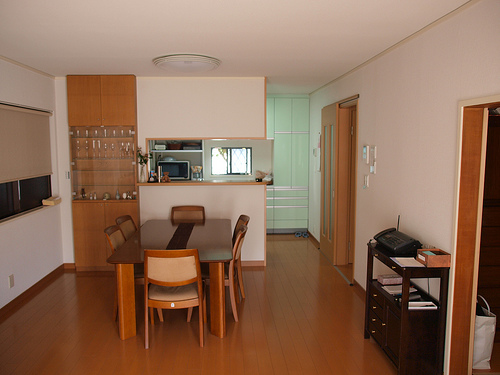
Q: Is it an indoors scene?
A: Yes, it is indoors.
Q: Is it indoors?
A: Yes, it is indoors.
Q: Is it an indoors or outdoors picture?
A: It is indoors.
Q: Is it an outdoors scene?
A: No, it is indoors.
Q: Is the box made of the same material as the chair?
A: Yes, both the box and the chair are made of wood.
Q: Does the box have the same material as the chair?
A: Yes, both the box and the chair are made of wood.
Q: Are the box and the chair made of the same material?
A: Yes, both the box and the chair are made of wood.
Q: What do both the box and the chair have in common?
A: The material, both the box and the chair are wooden.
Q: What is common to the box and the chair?
A: The material, both the box and the chair are wooden.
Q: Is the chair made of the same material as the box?
A: Yes, both the chair and the box are made of wood.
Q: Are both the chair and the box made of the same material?
A: Yes, both the chair and the box are made of wood.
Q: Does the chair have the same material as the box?
A: Yes, both the chair and the box are made of wood.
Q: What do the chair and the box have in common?
A: The material, both the chair and the box are wooden.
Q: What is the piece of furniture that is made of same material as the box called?
A: The piece of furniture is a chair.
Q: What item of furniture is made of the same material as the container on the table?
A: The chair is made of the same material as the box.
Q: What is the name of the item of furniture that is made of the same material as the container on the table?
A: The piece of furniture is a chair.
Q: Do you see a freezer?
A: No, there are no refrigerators.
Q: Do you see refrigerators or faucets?
A: No, there are no refrigerators or faucets.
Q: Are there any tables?
A: Yes, there is a table.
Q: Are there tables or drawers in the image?
A: Yes, there is a table.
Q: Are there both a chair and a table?
A: Yes, there are both a table and a chair.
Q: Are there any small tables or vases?
A: Yes, there is a small table.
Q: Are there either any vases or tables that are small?
A: Yes, the table is small.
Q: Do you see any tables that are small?
A: Yes, there is a small table.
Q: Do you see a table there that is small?
A: Yes, there is a table that is small.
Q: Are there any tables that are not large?
A: Yes, there is a small table.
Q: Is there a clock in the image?
A: No, there are no clocks.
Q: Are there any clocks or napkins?
A: No, there are no clocks or napkins.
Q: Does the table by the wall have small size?
A: Yes, the table is small.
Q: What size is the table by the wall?
A: The table is small.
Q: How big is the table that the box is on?
A: The table is small.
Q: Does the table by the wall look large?
A: No, the table is small.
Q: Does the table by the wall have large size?
A: No, the table is small.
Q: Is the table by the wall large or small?
A: The table is small.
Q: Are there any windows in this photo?
A: Yes, there is a window.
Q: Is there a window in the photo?
A: Yes, there is a window.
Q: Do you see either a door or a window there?
A: Yes, there is a window.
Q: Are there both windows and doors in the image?
A: Yes, there are both a window and a door.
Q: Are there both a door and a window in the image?
A: Yes, there are both a window and a door.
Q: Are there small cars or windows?
A: Yes, there is a small window.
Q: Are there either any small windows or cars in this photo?
A: Yes, there is a small window.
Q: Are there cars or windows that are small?
A: Yes, the window is small.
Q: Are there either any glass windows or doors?
A: Yes, there is a glass window.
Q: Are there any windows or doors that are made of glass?
A: Yes, the window is made of glass.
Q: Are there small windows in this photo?
A: Yes, there is a small window.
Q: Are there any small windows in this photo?
A: Yes, there is a small window.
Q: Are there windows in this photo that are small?
A: Yes, there is a small window.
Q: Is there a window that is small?
A: Yes, there is a window that is small.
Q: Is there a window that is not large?
A: Yes, there is a small window.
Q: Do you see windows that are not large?
A: Yes, there is a small window.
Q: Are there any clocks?
A: No, there are no clocks.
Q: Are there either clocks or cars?
A: No, there are no clocks or cars.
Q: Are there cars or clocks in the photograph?
A: No, there are no clocks or cars.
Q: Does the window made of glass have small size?
A: Yes, the window is small.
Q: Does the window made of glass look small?
A: Yes, the window is small.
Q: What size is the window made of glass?
A: The window is small.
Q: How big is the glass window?
A: The window is small.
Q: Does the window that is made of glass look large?
A: No, the window is small.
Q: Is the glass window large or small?
A: The window is small.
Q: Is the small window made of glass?
A: Yes, the window is made of glass.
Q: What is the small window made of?
A: The window is made of glass.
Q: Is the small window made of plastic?
A: No, the window is made of glass.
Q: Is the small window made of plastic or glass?
A: The window is made of glass.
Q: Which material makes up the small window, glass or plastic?
A: The window is made of glass.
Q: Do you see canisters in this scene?
A: No, there are no canisters.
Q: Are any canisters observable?
A: No, there are no canisters.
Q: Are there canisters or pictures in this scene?
A: No, there are no canisters or pictures.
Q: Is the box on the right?
A: Yes, the box is on the right of the image.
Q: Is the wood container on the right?
A: Yes, the box is on the right of the image.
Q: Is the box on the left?
A: No, the box is on the right of the image.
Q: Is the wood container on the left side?
A: No, the box is on the right of the image.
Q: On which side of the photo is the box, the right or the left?
A: The box is on the right of the image.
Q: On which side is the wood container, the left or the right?
A: The box is on the right of the image.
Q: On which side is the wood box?
A: The box is on the right of the image.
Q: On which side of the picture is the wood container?
A: The box is on the right of the image.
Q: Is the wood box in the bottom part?
A: Yes, the box is in the bottom of the image.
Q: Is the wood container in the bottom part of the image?
A: Yes, the box is in the bottom of the image.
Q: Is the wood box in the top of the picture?
A: No, the box is in the bottom of the image.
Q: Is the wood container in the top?
A: No, the box is in the bottom of the image.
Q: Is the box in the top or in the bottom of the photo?
A: The box is in the bottom of the image.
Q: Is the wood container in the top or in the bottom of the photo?
A: The box is in the bottom of the image.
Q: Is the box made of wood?
A: Yes, the box is made of wood.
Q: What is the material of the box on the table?
A: The box is made of wood.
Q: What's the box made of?
A: The box is made of wood.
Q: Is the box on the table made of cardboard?
A: No, the box is made of wood.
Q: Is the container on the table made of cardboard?
A: No, the box is made of wood.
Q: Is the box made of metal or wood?
A: The box is made of wood.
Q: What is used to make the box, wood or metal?
A: The box is made of wood.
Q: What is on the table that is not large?
A: The box is on the table.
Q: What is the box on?
A: The box is on the table.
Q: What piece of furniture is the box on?
A: The box is on the table.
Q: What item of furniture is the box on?
A: The box is on the table.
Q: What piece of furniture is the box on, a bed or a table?
A: The box is on a table.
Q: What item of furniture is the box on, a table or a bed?
A: The box is on a table.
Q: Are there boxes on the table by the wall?
A: Yes, there is a box on the table.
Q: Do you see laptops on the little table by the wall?
A: No, there is a box on the table.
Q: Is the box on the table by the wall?
A: Yes, the box is on the table.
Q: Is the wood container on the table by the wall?
A: Yes, the box is on the table.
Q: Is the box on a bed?
A: No, the box is on the table.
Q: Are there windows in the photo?
A: Yes, there is a window.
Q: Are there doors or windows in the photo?
A: Yes, there is a window.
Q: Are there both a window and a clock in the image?
A: No, there is a window but no clocks.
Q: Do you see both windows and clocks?
A: No, there is a window but no clocks.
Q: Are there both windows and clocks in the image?
A: No, there is a window but no clocks.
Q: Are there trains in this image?
A: No, there are no trains.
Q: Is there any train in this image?
A: No, there are no trains.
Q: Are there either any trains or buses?
A: No, there are no trains or buses.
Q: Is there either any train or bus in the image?
A: No, there are no trains or buses.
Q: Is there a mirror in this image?
A: No, there are no mirrors.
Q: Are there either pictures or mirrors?
A: No, there are no mirrors or pictures.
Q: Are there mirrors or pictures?
A: No, there are no mirrors or pictures.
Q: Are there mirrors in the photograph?
A: No, there are no mirrors.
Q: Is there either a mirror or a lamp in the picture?
A: No, there are no mirrors or lamps.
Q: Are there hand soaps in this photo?
A: No, there are no hand soaps.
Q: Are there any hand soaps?
A: No, there are no hand soaps.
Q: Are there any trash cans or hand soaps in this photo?
A: No, there are no hand soaps or trash cans.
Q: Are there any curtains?
A: No, there are no curtains.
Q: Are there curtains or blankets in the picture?
A: No, there are no curtains or blankets.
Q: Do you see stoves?
A: No, there are no stoves.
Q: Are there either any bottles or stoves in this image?
A: No, there are no stoves or bottles.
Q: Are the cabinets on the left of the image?
A: Yes, the cabinets are on the left of the image.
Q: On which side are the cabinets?
A: The cabinets are on the left of the image.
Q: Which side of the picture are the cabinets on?
A: The cabinets are on the left of the image.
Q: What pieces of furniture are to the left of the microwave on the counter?
A: The pieces of furniture are cabinets.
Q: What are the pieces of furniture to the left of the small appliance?
A: The pieces of furniture are cabinets.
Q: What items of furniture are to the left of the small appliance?
A: The pieces of furniture are cabinets.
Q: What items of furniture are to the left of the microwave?
A: The pieces of furniture are cabinets.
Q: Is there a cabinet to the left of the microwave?
A: Yes, there are cabinets to the left of the microwave.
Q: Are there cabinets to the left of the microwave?
A: Yes, there are cabinets to the left of the microwave.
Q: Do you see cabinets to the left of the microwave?
A: Yes, there are cabinets to the left of the microwave.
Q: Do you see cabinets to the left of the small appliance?
A: Yes, there are cabinets to the left of the microwave.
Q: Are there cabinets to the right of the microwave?
A: No, the cabinets are to the left of the microwave.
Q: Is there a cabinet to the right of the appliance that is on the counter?
A: No, the cabinets are to the left of the microwave.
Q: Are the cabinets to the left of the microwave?
A: Yes, the cabinets are to the left of the microwave.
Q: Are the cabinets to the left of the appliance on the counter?
A: Yes, the cabinets are to the left of the microwave.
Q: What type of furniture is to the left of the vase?
A: The pieces of furniture are cabinets.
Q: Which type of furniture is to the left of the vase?
A: The pieces of furniture are cabinets.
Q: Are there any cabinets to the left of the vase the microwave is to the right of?
A: Yes, there are cabinets to the left of the vase.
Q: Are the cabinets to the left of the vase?
A: Yes, the cabinets are to the left of the vase.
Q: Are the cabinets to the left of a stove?
A: No, the cabinets are to the left of the vase.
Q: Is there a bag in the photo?
A: Yes, there is a bag.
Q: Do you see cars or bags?
A: Yes, there is a bag.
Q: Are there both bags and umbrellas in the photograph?
A: No, there is a bag but no umbrellas.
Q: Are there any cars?
A: No, there are no cars.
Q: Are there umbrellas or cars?
A: No, there are no cars or umbrellas.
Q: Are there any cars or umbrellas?
A: No, there are no cars or umbrellas.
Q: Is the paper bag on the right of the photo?
A: Yes, the bag is on the right of the image.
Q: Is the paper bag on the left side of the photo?
A: No, the bag is on the right of the image.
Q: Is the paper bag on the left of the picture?
A: No, the bag is on the right of the image.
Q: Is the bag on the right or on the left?
A: The bag is on the right of the image.